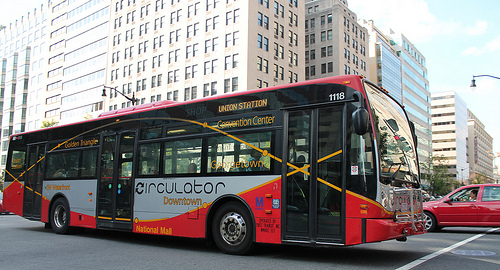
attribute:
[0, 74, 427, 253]
bus — black, red, grey, orange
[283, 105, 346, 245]
side doors — closed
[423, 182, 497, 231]
car — red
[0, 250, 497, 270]
street — grey, clean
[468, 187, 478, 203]
person — driving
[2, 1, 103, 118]
building — white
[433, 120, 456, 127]
windows — large